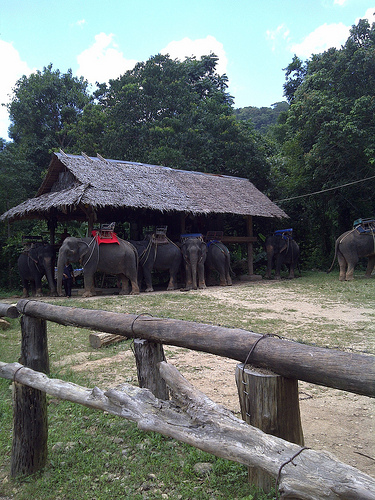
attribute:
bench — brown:
[207, 227, 227, 241]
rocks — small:
[94, 447, 178, 486]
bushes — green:
[264, 56, 338, 181]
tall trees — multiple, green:
[0, 9, 370, 269]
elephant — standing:
[128, 233, 182, 292]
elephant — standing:
[176, 230, 210, 294]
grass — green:
[8, 271, 368, 489]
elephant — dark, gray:
[264, 234, 301, 279]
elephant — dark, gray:
[204, 241, 231, 285]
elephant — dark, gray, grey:
[56, 235, 140, 296]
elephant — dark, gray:
[18, 241, 55, 295]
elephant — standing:
[205, 235, 239, 289]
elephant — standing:
[256, 230, 303, 282]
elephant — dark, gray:
[322, 228, 372, 282]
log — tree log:
[5, 357, 374, 498]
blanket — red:
[91, 228, 118, 244]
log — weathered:
[84, 358, 343, 473]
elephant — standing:
[52, 231, 145, 300]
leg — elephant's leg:
[125, 259, 141, 295]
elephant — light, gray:
[41, 224, 152, 285]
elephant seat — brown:
[141, 223, 182, 297]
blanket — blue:
[209, 238, 224, 249]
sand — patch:
[267, 280, 320, 320]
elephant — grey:
[328, 217, 374, 281]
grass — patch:
[284, 270, 374, 318]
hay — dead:
[169, 176, 196, 195]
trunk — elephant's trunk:
[51, 254, 74, 292]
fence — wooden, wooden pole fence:
[20, 301, 372, 487]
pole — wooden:
[162, 313, 319, 374]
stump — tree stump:
[11, 319, 51, 477]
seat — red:
[94, 229, 120, 243]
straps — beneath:
[150, 245, 160, 268]